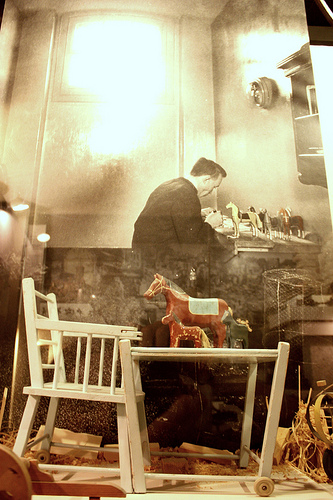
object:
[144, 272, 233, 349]
horse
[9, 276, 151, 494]
chair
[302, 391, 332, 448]
wire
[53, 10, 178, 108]
window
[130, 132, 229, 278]
man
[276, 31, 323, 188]
shelve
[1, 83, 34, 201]
wall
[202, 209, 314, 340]
table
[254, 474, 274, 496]
wheel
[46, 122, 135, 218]
shelf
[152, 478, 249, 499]
floor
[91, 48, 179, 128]
sun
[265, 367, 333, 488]
basket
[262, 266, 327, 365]
net